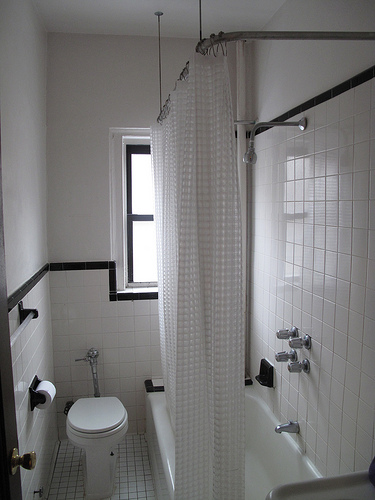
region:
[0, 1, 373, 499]
a pristine looking bathroom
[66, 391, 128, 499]
a white commode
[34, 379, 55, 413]
a roll of toilet paper on a rack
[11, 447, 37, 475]
a doorknob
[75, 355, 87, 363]
the flusher on a commode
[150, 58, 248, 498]
a white shower curtain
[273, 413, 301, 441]
a nozzle on a bathtub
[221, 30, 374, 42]
a shower curtain rod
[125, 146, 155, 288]
a window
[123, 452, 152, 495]
a tiled floor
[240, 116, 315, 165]
Chrome shower head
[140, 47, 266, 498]
Vinyl white shower curtain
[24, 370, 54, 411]
Toilet Paper Roll with black holder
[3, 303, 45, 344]
Towel Bar attached to Tile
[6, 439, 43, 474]
Brass Door Knob on Door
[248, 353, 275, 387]
Black tile soap holder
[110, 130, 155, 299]
Glass window with black tile outline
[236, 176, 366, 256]
Subway tile backsplash for shower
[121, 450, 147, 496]
Small white tile with black groute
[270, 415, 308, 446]
Chrome water faucet attached to bathtub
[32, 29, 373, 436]
WHITE AND BLACK TILES BATHROOM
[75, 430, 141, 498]
WHITE PORCELAIN TOILET BOWL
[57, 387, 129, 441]
WHITE WOODEN TOILET LID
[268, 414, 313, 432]
SILVER BATH TUB FAUCET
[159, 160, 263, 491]
WHITE AND TRANSPARENT SHOWER CURTAINS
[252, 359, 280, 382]
BLACK PORCELAIN SOAP HOLDER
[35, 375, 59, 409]
WHITE FULL ROLL OF TOILET PAPER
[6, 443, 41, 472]
GOLD COLORED DOOR NOB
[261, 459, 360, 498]
STAINLESS STEEL SHOWER BAR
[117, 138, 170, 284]
OPACHE WINDOW IN BATHROOM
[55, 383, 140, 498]
white toilet in bathroom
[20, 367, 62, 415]
toilet paper roll on a wall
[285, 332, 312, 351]
silver metal shower fixture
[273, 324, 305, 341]
silver metal shower fixture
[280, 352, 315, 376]
silver metal shower fixture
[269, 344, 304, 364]
silver metal shower fixture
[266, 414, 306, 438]
silver metal shower fixture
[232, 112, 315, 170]
silver metal shower fixture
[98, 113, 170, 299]
window with white trim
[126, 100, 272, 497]
clear plastic shower curtain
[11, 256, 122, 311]
black tile trim on the wall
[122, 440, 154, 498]
white tile floor with small tiles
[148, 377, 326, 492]
a white bathtub on the floor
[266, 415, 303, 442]
water faucet on the wall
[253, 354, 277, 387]
a black soap dish on the wall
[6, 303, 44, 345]
a towel rack on the wall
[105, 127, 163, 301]
a window above the tub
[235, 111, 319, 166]
a shower head on the wall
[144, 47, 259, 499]
a shower curtain with a design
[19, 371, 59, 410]
toilet paper on a holder